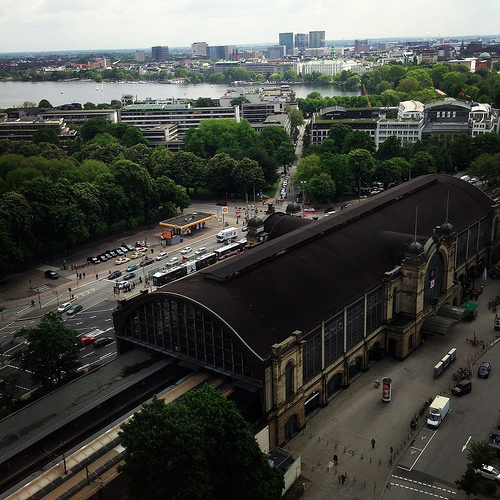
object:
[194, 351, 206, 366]
window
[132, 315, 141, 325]
window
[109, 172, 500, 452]
building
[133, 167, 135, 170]
lead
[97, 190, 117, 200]
lead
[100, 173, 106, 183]
lead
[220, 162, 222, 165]
lead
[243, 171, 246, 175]
lead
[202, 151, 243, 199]
plant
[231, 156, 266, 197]
plant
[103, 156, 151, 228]
plant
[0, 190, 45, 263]
plant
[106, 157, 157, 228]
plant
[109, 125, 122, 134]
leaf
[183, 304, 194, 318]
window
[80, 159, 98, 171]
leaf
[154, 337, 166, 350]
window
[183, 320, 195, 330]
window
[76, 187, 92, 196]
leaf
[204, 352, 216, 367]
window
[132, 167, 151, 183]
leaf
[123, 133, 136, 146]
leaf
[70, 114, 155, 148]
plant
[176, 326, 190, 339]
glass window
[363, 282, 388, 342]
window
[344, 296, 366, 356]
window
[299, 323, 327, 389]
window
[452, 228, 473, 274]
window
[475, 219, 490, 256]
window